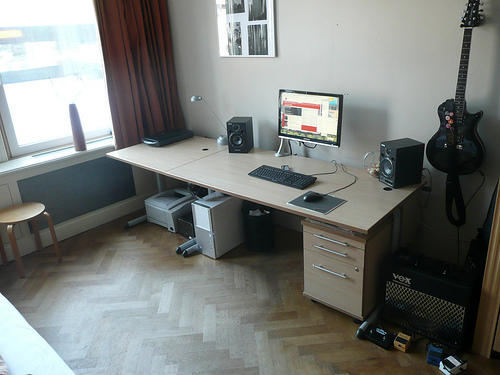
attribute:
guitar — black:
[428, 1, 483, 197]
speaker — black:
[215, 111, 259, 158]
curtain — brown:
[83, 0, 191, 144]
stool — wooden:
[0, 197, 80, 288]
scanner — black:
[132, 119, 195, 154]